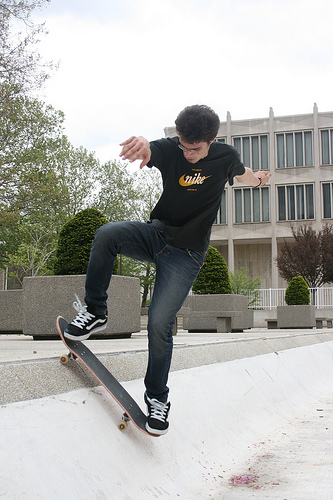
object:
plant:
[54, 208, 119, 275]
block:
[22, 274, 141, 340]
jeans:
[84, 219, 206, 404]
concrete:
[0, 285, 330, 498]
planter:
[277, 304, 315, 328]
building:
[162, 105, 333, 320]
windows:
[276, 180, 317, 222]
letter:
[178, 173, 212, 186]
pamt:
[192, 243, 232, 294]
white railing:
[38, 298, 170, 396]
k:
[195, 173, 202, 185]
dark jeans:
[84, 220, 208, 403]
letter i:
[192, 172, 197, 185]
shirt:
[145, 135, 244, 250]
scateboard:
[56, 310, 160, 436]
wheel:
[56, 349, 73, 368]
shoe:
[144, 391, 171, 436]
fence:
[247, 287, 332, 312]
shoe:
[63, 293, 108, 341]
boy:
[56, 105, 266, 438]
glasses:
[177, 138, 210, 154]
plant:
[284, 275, 311, 305]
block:
[277, 305, 316, 329]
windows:
[285, 132, 296, 169]